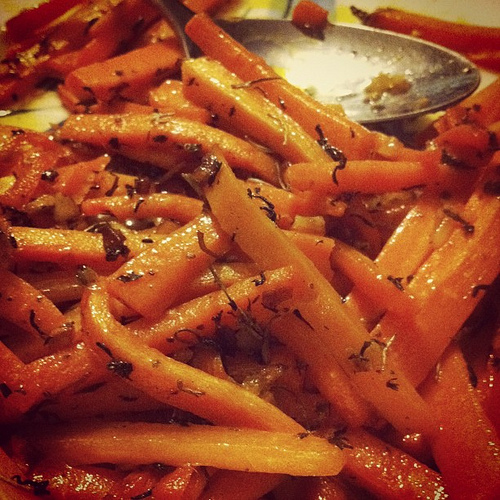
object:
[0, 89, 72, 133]
dish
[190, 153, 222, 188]
herb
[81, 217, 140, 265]
herbs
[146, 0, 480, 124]
spoon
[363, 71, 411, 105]
carrots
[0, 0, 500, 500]
carrots